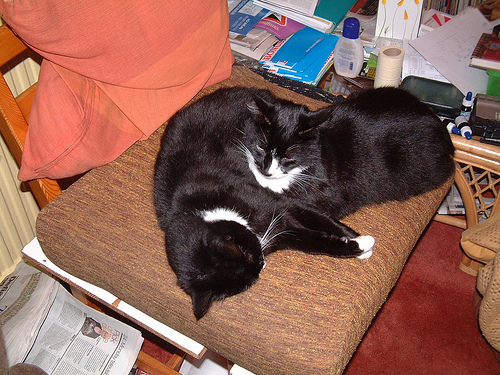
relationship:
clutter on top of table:
[231, 0, 498, 110] [230, 0, 498, 275]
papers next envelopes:
[244, 2, 340, 34] [262, 23, 343, 88]